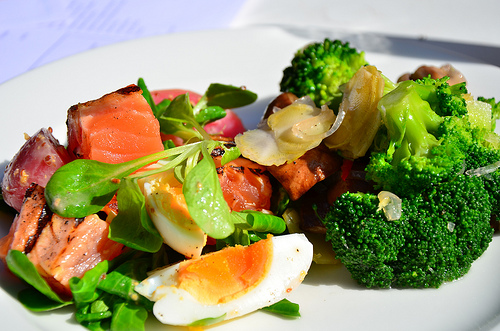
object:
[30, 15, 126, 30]
floor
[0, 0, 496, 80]
table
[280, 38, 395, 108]
brocollis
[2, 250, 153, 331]
green vegetable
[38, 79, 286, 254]
green vegetable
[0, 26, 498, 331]
plate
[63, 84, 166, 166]
carrot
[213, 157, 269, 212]
tomatoe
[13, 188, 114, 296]
carrot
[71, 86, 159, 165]
meat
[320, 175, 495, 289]
broccoli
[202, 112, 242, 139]
tomato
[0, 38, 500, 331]
food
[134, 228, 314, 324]
egg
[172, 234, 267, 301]
orange york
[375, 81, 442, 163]
stalks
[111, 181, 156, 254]
leaves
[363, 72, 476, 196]
broccoli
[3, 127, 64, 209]
pieces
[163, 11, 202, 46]
bad sentence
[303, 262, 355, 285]
shadow